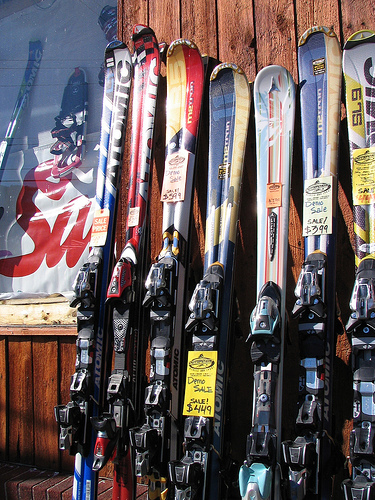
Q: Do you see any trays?
A: No, there are no trays.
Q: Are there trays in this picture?
A: No, there are no trays.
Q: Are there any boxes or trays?
A: No, there are no trays or boxes.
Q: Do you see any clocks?
A: No, there are no clocks.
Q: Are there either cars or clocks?
A: No, there are no clocks or cars.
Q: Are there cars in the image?
A: No, there are no cars.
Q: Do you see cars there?
A: No, there are no cars.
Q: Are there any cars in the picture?
A: No, there are no cars.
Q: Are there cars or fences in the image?
A: No, there are no cars or fences.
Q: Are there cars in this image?
A: No, there are no cars.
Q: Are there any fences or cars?
A: No, there are no cars or fences.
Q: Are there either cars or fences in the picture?
A: No, there are no cars or fences.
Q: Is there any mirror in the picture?
A: No, there are no mirrors.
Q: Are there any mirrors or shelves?
A: No, there are no mirrors or shelves.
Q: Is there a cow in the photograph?
A: No, there are no cows.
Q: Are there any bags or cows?
A: No, there are no cows or bags.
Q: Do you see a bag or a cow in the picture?
A: No, there are no cows or bags.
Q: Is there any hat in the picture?
A: Yes, there is a hat.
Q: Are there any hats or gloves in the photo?
A: Yes, there is a hat.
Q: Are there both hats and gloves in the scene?
A: No, there is a hat but no gloves.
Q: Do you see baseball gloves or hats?
A: Yes, there is a baseball hat.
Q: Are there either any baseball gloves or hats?
A: Yes, there is a baseball hat.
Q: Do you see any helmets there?
A: No, there are no helmets.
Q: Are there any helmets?
A: No, there are no helmets.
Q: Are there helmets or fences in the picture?
A: No, there are no helmets or fences.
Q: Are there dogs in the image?
A: No, there are no dogs.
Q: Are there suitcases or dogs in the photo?
A: No, there are no dogs or suitcases.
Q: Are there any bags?
A: No, there are no bags.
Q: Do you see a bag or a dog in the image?
A: No, there are no bags or dogs.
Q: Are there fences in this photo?
A: No, there are no fences.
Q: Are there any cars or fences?
A: No, there are no fences or cars.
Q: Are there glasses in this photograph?
A: No, there are no glasses.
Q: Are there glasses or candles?
A: No, there are no glasses or candles.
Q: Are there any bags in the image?
A: No, there are no bags.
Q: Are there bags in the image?
A: No, there are no bags.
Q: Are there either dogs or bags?
A: No, there are no bags or dogs.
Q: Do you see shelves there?
A: No, there are no shelves.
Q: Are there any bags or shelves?
A: No, there are no shelves or bags.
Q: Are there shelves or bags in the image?
A: No, there are no shelves or bags.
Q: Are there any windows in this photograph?
A: Yes, there is a window.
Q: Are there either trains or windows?
A: Yes, there is a window.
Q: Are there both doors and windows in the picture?
A: No, there is a window but no doors.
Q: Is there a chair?
A: No, there are no chairs.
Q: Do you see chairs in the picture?
A: No, there are no chairs.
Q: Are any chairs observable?
A: No, there are no chairs.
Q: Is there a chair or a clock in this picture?
A: No, there are no chairs or clocks.